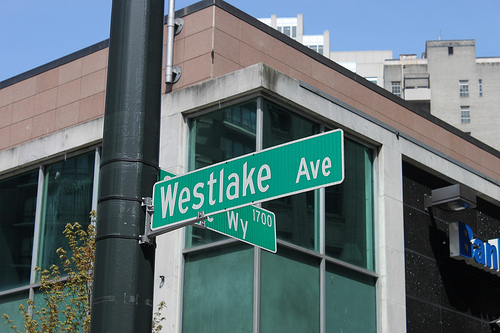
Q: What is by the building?
A: Black pole.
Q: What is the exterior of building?
A: Red.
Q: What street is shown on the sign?
A: Westlake Ave.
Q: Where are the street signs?
A: On a pole.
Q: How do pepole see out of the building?
A: Windows.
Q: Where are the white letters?
A: Strree sign.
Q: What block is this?
A: 1700.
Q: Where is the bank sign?
A: Black part of the building.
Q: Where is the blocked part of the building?
A: Top.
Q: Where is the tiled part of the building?
A: Black part.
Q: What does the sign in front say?
A: Westlake Ave.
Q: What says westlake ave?
A: The sign.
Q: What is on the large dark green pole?
A: Street signs.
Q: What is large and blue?
A: The sky.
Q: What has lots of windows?
A: The buildings.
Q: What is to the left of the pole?
A: Bush.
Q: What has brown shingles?
A: Building roof.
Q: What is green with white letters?
A: Street sign.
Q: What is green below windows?
A: Building side.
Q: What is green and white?
A: Sign.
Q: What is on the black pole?
A: Sign.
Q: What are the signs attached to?
A: Black pole.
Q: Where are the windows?
A: On building.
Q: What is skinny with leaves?
A: Tree branches.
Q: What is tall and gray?
A: Buildings.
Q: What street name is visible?
A: Westlake Ave.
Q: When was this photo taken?
A: During the daytime.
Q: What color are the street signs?
A: Green.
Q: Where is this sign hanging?
A: On a black post.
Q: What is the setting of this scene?
A: A city.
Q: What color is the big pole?
A: Black.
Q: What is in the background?
A: Tall buildings.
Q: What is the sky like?
A: Clear.